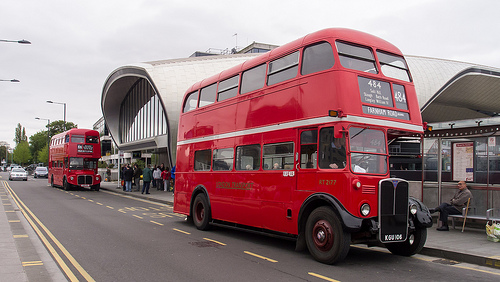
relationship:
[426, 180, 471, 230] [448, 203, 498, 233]
man sitting in chair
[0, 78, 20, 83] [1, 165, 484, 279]
light pole hanging over street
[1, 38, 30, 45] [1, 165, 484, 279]
light pole hanging over street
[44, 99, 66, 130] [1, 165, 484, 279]
light pole hanging over street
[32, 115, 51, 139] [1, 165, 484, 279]
light pole hanging over street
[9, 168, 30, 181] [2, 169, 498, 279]
car driving on road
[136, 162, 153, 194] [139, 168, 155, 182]
man wearing jacket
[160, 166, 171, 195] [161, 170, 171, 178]
man wearing red jacket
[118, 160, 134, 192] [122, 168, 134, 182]
man wearing jacket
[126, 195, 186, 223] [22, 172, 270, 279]
lettering on street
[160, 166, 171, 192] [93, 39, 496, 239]
man going into building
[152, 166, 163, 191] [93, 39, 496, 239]
person going into building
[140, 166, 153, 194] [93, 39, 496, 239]
man going into building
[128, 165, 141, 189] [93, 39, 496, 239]
person going into building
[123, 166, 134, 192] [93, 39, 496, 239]
man going into building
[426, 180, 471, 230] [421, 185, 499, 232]
man sitting on bench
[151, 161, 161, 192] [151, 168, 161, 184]
person wearing jacket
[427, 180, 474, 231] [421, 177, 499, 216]
man sitting on bench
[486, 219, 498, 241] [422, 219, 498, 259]
bag on platform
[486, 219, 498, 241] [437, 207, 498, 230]
bag in front of bench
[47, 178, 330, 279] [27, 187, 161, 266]
markings on road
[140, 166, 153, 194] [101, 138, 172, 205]
man waiting platform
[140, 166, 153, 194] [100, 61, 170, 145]
man standing under shade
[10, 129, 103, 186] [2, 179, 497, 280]
traffic on road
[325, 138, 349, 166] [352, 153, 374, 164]
driver sitting in steering wheel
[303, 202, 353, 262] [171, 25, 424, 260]
tire on bus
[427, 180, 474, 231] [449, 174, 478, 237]
man sits on beach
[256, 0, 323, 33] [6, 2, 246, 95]
clouds in sky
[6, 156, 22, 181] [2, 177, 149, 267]
car on road